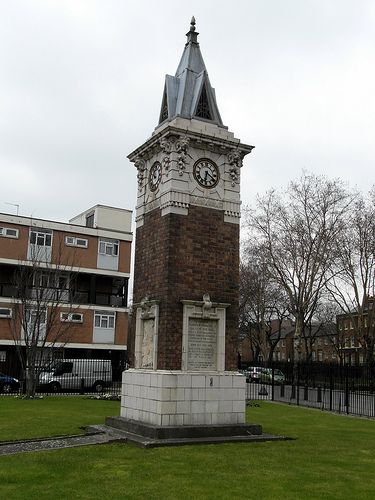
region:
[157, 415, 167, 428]
white block on tower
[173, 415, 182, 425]
white block on tower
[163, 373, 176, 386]
white block on tower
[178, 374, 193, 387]
white block on tower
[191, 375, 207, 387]
white block on tower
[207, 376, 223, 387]
white block on tower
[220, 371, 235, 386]
white block on tower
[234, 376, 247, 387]
white block on tower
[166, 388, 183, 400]
white block on tower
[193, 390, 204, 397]
white block on tower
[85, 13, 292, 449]
a small clock tower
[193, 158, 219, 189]
a black and white clock face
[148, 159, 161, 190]
a black and white clock face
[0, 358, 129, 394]
a black wrought iron fence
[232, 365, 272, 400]
a black wrought iron fence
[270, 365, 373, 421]
a black wrought iron fence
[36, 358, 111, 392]
a white van on street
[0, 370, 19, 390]
a blue car on street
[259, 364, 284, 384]
a green car on street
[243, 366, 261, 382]
a silver SUV on street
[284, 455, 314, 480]
Small patch of green grass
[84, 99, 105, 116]
Small patch of the white sky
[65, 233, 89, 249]
Air conditioning vent on the building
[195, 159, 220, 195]
Clock on clock tower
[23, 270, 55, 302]
Branches on the tree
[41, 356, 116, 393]
White vehicle that is parked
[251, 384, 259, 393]
Small part of the gray street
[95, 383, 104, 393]
Back left wheel on vehicle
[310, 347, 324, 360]
A couple of windows on the building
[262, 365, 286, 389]
Light green car on the street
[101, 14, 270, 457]
A structure is in the middle of a yard.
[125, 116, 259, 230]
Two clocks are on a structure.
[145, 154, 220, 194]
The colors of two clocks are white, black, and brown.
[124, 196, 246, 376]
Brown bricks can be seen on a structure.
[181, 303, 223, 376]
Writing can be seen on a structure.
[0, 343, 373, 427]
A fence surrounds a yard.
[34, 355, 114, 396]
A van is behind a fence.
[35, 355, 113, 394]
The colors of a van are white and black.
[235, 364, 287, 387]
Vehicles are near a street.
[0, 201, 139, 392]
A building is in the background.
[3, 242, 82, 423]
the trees are bare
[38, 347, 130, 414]
the van is white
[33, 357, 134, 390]
the van is white